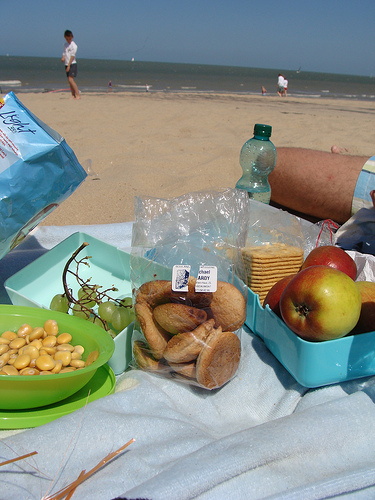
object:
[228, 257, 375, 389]
box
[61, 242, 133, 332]
vine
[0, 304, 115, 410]
bowl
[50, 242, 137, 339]
grapes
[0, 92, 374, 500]
ground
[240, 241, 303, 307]
crackers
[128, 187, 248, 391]
bag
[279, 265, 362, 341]
apple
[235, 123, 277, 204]
bottle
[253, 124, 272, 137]
lid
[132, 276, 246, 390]
cookies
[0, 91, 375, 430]
food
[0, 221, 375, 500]
blanket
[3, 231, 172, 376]
container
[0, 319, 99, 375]
beans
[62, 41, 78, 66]
shirt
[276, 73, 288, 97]
people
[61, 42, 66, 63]
arm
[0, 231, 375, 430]
assorted foods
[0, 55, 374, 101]
ocean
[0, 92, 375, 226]
beach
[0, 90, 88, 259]
bag of potato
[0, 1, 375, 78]
blue sky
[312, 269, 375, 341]
some green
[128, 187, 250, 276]
bread in a bag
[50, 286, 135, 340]
ry full of grapes."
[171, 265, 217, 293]
ripped label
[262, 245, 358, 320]
large red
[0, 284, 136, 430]
large green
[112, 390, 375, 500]
white shirt standi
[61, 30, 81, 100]
arm of a person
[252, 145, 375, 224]
arm of a person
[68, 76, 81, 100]
leg of a person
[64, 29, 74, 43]
hair of a person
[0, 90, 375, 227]
sand on a beach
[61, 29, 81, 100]
body of a person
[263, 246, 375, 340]
colored apple